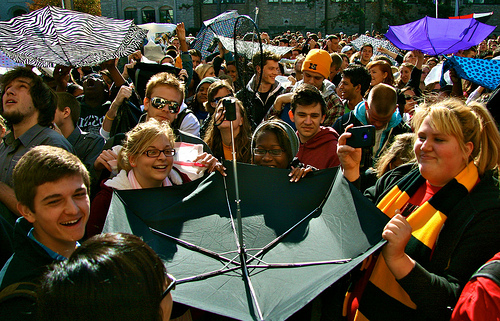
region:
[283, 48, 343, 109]
Man with orange hat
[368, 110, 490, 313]
woman wearing black and orange scarf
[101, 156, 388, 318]
upside down and open green umbrella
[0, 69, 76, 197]
man wearing grey shirt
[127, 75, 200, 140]
man wearing sun glasses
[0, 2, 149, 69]
zebra striped upside down umbrella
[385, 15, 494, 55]
purple upside down umbrella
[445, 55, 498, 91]
blue polka dot upside down umbrella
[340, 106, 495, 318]
woman holding camera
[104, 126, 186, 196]
woman wearing glasses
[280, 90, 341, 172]
Man wearing a red hoodie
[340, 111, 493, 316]
Woman wearing a green and yellow scarf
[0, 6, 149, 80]
Zebra print umbrella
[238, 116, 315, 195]
Woman wearing a green hat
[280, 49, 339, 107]
Man wearing a yellow hat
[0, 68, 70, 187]
Man wearing a gray shirt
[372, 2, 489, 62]
Purple umbrella turned upside down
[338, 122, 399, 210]
Camera in woman's hand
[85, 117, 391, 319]
Green umbrella turned upside down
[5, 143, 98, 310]
Man on the left smiling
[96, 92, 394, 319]
A green umbrella upside down.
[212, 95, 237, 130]
The black handle of a green umbrella.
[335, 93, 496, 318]
A chubby white chick holding a phone.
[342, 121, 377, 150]
An iPhone held by a blonde.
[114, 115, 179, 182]
A beautiful happy little girl.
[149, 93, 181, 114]
A pair of fashionable sunglasses.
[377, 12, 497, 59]
A purple umbrella held up side down.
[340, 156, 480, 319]
The beautiful scarf around a woman's neck.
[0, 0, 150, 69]
A white umbrella with dozens of black stripes.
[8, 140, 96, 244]
A young white guy smiling at a friend.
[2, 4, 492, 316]
People holding umbrellas upsidedown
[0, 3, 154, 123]
An upside down zebra print umbrella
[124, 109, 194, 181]
A girl wearing glasses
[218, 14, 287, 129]
A person holding a fishing net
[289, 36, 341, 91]
A young man wearing a yellow winter hat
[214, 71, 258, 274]
An umbrella handle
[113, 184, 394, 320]
The underside of an umbrella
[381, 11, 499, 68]
An upsidedown purple umbrella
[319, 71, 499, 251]
A woman holding a cell phone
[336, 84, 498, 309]
A woman wearing a yellow and black scarf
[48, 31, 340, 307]
the umbrella is green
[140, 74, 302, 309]
the umbrella is green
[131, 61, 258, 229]
the umbrella is green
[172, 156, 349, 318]
the umbrella is green